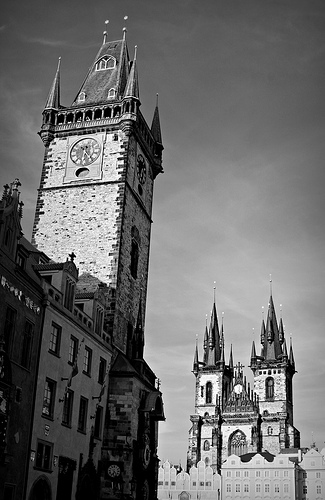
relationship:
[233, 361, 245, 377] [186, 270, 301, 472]
cross on top cathedral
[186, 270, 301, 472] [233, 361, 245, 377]
cathedral has cross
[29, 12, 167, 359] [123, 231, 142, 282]
clock tower has window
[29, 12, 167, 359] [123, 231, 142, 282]
clock tower have window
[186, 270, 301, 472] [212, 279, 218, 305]
cathedral have spire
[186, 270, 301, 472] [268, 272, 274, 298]
cathedral have spire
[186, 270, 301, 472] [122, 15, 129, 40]
cathedral have spiers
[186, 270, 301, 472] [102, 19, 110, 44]
cathedral have spiers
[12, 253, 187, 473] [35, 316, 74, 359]
cathedral have window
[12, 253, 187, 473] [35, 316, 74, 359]
cathedral has window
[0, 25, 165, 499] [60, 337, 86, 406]
cathedral has flag pole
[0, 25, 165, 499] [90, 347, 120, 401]
cathedral has flag pole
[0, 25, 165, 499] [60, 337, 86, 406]
cathedral have flag pole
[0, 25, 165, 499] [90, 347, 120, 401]
cathedral have flag pole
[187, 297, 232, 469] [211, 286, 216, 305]
building have antenna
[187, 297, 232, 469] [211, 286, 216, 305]
building has antenna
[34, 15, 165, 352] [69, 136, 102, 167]
building has clock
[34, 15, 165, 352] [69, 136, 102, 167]
building have clock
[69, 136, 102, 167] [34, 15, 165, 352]
clock in building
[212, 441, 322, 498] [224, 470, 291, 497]
building have windows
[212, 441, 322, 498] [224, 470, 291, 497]
building has windows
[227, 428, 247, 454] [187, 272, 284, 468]
door in front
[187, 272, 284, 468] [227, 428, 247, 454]
front have door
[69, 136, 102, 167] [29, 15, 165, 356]
clock is building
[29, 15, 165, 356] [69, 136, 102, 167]
building has clock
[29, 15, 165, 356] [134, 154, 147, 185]
building has clock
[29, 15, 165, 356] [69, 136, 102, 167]
building have clock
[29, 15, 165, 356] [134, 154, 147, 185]
building have clock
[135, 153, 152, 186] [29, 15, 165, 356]
clock on the side building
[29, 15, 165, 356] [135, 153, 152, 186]
building has clock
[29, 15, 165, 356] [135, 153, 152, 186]
building have clock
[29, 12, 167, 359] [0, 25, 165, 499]
clock tower on cathedral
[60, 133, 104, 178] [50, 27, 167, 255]
clock on tower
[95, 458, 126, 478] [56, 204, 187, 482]
clock on building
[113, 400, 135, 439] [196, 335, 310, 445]
bricks on building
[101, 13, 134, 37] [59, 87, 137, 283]
light on building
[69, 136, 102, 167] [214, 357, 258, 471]
clock on tower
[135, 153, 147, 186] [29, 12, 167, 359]
clock on clock tower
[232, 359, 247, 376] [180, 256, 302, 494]
cross atop clock tower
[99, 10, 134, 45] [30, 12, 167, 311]
spiers on clock tower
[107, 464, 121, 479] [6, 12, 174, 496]
clock at bottom of near tower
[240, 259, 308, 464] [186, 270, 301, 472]
right towerl of far cathedral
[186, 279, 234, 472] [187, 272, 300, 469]
tower of far church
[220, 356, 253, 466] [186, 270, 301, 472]
middle tower of far cathedral